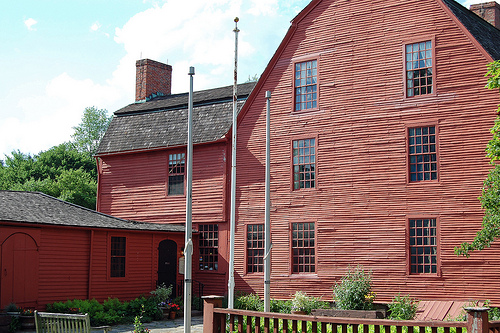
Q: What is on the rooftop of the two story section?
A: A chimney.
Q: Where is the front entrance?
A: The one-story section of the building.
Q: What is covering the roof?
A: Shingles.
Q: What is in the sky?
A: Clouds.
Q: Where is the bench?
A: In the yard.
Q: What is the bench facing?
A: The side of the building.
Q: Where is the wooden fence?
A: Across from the bench.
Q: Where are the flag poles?
A: In the yard.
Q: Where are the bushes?
A: Alongside the building.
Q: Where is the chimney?
A: On top of the roof.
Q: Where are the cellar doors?
A: On the side of the house.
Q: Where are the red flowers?
A: Near the door of the building.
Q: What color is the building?
A: Red.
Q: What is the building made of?
A: Wood.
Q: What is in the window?
A: Curtain.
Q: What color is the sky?
A: Blue.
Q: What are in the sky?
A: Clouds.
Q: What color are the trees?
A: Green.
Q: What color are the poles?
A: White.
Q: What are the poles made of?
A: Metal.